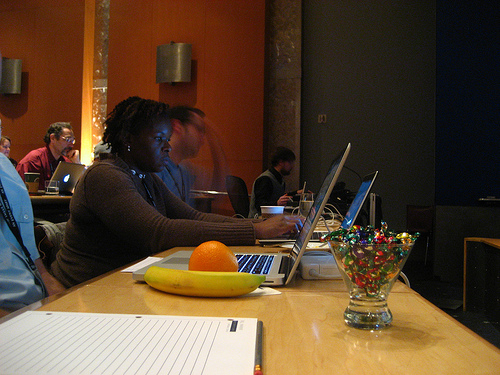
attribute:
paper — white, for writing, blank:
[0, 309, 263, 374]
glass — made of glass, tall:
[318, 222, 421, 334]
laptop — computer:
[131, 140, 353, 289]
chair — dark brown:
[222, 173, 250, 220]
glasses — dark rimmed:
[186, 117, 206, 134]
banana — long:
[142, 265, 267, 300]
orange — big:
[190, 237, 240, 276]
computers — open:
[130, 140, 381, 289]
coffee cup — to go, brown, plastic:
[259, 203, 285, 221]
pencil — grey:
[251, 319, 268, 375]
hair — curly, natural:
[103, 93, 171, 156]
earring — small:
[125, 143, 134, 155]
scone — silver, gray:
[155, 36, 196, 89]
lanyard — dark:
[128, 169, 156, 210]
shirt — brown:
[49, 154, 256, 291]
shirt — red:
[14, 146, 68, 181]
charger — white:
[300, 251, 411, 287]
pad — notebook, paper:
[0, 308, 264, 373]